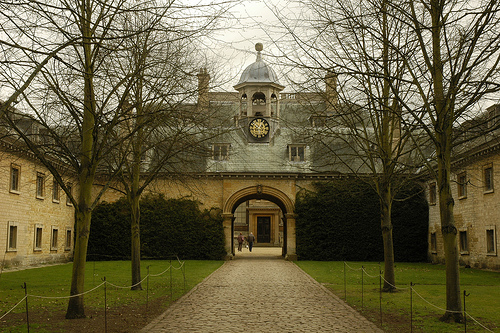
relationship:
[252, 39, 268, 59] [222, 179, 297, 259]
cupola above archway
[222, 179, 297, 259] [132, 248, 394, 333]
entryway over walkway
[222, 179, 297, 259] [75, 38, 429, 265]
entryway built into building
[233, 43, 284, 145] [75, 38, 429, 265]
tower on top of building